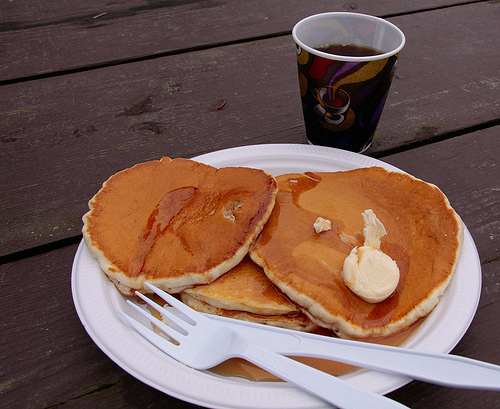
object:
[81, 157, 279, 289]
pancakes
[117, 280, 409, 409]
fork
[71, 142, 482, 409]
plate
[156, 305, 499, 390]
knife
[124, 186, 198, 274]
syrup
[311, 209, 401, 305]
butter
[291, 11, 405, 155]
cup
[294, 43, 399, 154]
coffee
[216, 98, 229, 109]
stem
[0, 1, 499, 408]
table